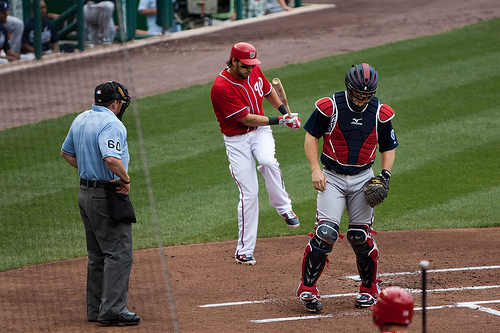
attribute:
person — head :
[179, 37, 314, 257]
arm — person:
[101, 138, 145, 191]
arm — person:
[239, 110, 279, 129]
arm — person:
[273, 129, 333, 203]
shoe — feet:
[97, 311, 136, 325]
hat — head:
[227, 40, 262, 68]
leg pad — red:
[296, 216, 340, 293]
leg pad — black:
[348, 222, 379, 292]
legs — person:
[219, 135, 300, 266]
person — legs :
[296, 60, 401, 310]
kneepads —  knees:
[310, 223, 368, 253]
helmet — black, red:
[345, 60, 377, 93]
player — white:
[206, 39, 302, 268]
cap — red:
[231, 40, 261, 65]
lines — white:
[197, 291, 304, 331]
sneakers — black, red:
[355, 277, 377, 307]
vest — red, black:
[321, 92, 380, 174]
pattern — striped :
[418, 123, 480, 213]